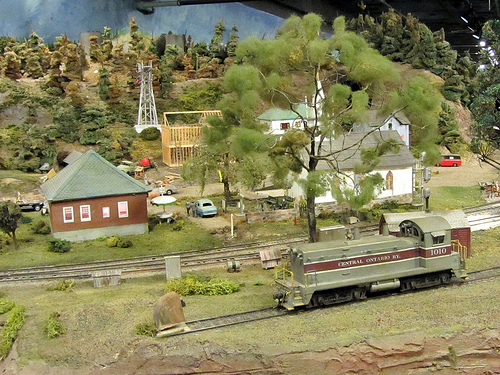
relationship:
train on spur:
[273, 213, 473, 316] [151, 263, 500, 343]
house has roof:
[37, 149, 153, 248] [37, 147, 158, 202]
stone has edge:
[2, 175, 23, 190] [4, 174, 14, 187]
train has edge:
[273, 213, 473, 316] [275, 266, 435, 314]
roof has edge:
[37, 147, 158, 202] [46, 187, 157, 207]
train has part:
[273, 213, 473, 316] [271, 258, 295, 289]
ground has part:
[4, 38, 495, 365] [89, 293, 118, 320]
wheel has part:
[32, 205, 44, 211] [33, 206, 46, 214]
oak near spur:
[181, 11, 448, 250] [151, 263, 500, 343]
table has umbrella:
[154, 210, 175, 225] [151, 190, 178, 215]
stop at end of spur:
[152, 287, 192, 338] [151, 263, 500, 343]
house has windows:
[37, 149, 153, 248] [58, 199, 134, 225]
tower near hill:
[132, 56, 165, 136] [9, 66, 335, 141]